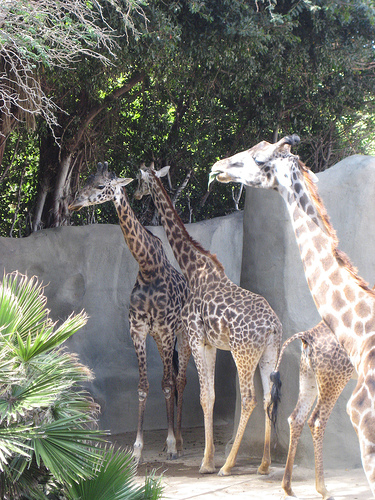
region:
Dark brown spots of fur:
[133, 291, 148, 303]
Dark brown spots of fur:
[134, 310, 154, 327]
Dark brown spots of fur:
[150, 292, 166, 309]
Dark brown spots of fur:
[141, 266, 158, 288]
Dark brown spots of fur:
[126, 235, 137, 245]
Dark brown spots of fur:
[121, 220, 136, 247]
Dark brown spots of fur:
[115, 199, 132, 220]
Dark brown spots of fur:
[125, 216, 137, 234]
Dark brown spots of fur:
[133, 220, 166, 260]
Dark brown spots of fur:
[197, 302, 274, 348]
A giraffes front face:
[67, 158, 125, 213]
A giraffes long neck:
[113, 197, 169, 268]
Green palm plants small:
[2, 264, 170, 497]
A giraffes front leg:
[183, 331, 216, 475]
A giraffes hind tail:
[269, 330, 309, 423]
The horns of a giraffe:
[274, 130, 300, 153]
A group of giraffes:
[13, 161, 370, 478]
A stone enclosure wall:
[2, 227, 236, 438]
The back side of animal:
[226, 280, 287, 491]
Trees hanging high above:
[6, 61, 357, 191]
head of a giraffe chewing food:
[207, 133, 302, 193]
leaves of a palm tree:
[0, 269, 167, 498]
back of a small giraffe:
[271, 319, 352, 499]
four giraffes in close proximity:
[66, 134, 373, 498]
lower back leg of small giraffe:
[281, 413, 303, 497]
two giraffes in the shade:
[70, 161, 283, 481]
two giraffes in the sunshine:
[209, 134, 373, 497]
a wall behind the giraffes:
[0, 207, 244, 435]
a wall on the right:
[237, 153, 372, 462]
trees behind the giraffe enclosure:
[2, 2, 373, 233]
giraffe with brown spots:
[65, 156, 192, 467]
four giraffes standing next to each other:
[67, 130, 374, 498]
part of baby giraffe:
[265, 313, 356, 498]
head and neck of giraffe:
[202, 128, 374, 377]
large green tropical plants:
[0, 262, 166, 498]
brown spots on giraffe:
[197, 292, 255, 333]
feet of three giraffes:
[124, 431, 337, 499]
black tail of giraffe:
[265, 367, 284, 446]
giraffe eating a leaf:
[203, 130, 374, 318]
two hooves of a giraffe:
[259, 479, 337, 494]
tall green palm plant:
[1, 314, 108, 483]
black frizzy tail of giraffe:
[207, 364, 288, 461]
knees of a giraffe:
[70, 378, 189, 440]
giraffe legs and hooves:
[115, 346, 290, 497]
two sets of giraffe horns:
[95, 153, 160, 177]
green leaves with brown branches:
[43, 15, 311, 151]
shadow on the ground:
[130, 439, 236, 485]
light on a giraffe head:
[182, 125, 316, 195]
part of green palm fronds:
[52, 437, 164, 489]